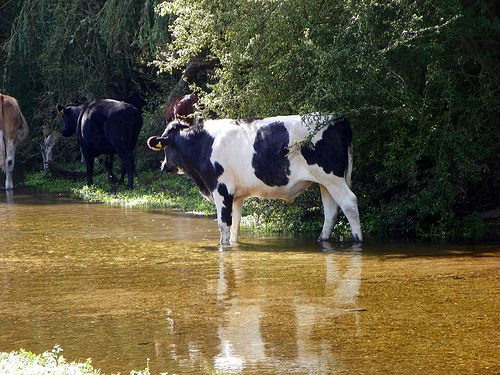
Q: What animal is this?
A: Cow.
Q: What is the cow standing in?
A: Water.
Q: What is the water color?
A: Brown.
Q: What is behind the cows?
A: Trees.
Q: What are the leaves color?
A: Green.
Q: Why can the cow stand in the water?
A: It is shallow.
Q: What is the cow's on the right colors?
A: Black and white.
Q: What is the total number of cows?
A: 4.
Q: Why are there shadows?
A: Sunny.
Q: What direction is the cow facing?
A: Left.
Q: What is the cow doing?
A: Standing in the water.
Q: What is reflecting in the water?
A: The cow.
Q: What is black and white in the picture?
A: One of the cows.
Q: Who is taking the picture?
A: A photographer.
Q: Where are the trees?
A: On the right side of the cows.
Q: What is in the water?
A: Rocks.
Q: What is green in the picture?
A: The trees.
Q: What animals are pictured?
A: Cows.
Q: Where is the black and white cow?
A: In the water.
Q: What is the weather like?
A: Sunny.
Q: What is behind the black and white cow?
A: Trees and other greenery.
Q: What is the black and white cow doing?
A: Standing.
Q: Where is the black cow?
A: To the left of the brown and white cow.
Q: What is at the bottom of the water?
A: Rocks.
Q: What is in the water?
A: Cows.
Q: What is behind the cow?
A: Trees.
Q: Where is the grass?
A: Under the water.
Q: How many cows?
A: 4.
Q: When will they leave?
A: Now.